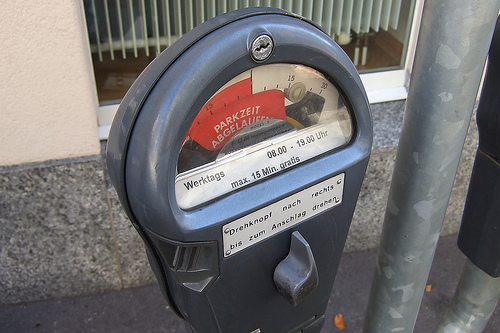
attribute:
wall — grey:
[16, 191, 176, 295]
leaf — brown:
[319, 313, 357, 326]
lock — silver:
[252, 33, 275, 63]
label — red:
[182, 76, 289, 161]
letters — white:
[206, 103, 277, 155]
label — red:
[186, 76, 286, 155]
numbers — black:
[192, 87, 253, 127]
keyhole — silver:
[249, 33, 273, 62]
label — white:
[221, 174, 347, 259]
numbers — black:
[252, 125, 336, 177]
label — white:
[175, 115, 345, 207]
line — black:
[248, 68, 256, 101]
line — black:
[192, 118, 200, 128]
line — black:
[205, 110, 215, 120]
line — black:
[235, 92, 247, 106]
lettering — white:
[202, 100, 267, 150]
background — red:
[182, 79, 292, 153]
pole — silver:
[361, 2, 497, 330]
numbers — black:
[246, 150, 306, 180]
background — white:
[173, 117, 353, 212]